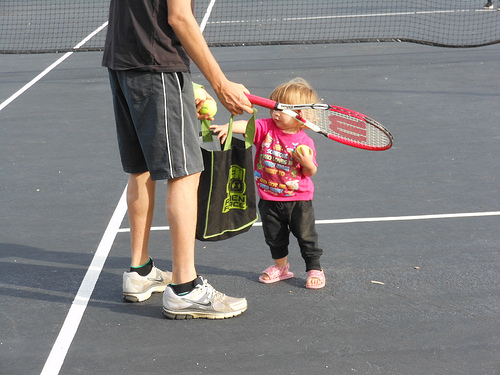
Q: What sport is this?
A: Tennis.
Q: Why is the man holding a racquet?
A: To hit the ball.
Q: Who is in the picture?
A: Two people.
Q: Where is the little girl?
A: Next to the man.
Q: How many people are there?
A: Two.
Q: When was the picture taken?
A: Daytime.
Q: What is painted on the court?
A: Boundary lines.